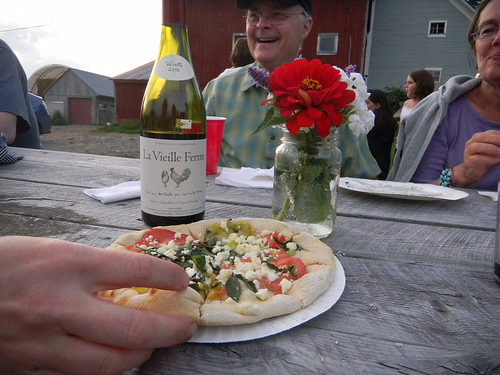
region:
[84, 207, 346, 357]
Small pizza over a white dish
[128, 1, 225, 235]
Bottle of wine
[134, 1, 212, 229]
Bottle of wine is half empty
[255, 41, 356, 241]
Jar with a flowers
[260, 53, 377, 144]
Red and white flowers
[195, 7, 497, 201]
Couple sitting on a table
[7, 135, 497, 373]
Table is made of wood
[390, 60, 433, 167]
A girl behind a couple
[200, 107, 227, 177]
Red plastic glass in front of man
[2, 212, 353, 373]
Hand taking a pizza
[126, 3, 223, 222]
Wine bottle on the table.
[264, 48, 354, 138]
Red flower in the jar.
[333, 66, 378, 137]
White flowers in the jar.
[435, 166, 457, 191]
Turquoise flower medallion on woman's wrist.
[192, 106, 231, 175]
Red plastic cup behind the wine bottle.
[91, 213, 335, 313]
Dough with cheese and tomatoes.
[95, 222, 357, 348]
White paper plate dough and tomato dish is on.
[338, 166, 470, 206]
Empty paper plate in front of woman in purple shirt.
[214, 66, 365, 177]
Yellow and blue shirt worn by older man.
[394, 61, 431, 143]
Young girl in white tank top behind older woman in purple shirt.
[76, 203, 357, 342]
small margherita pizza on plate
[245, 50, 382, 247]
flower arrangement in glass jar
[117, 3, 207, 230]
wine bottle with chickens on label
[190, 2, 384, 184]
man in plaid shird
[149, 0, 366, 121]
dark red building in background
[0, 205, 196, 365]
hand reaching for pizza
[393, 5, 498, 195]
woman with purple shirt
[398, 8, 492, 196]
woman with grey sweater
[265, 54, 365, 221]
red gerber daisy in jar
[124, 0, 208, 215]
red wine in bottle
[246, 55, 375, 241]
red zinnia in mason jar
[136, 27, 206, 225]
green glass bottle on table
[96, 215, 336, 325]
personal size pizza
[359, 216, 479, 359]
wood grain of picnic table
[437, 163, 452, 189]
turquoise bracelet on woman's wrist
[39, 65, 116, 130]
wood structure in background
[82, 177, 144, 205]
folded up white napkin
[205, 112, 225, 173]
red Solo cup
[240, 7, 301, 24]
eyeglasses on man's face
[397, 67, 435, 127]
young girl in white tank top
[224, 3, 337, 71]
the man is smiling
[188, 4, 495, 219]
people are in the photo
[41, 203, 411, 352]
pizza is on the table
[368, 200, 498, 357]
the table is of wood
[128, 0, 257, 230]
wine is in the bottle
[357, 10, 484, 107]
buildings are in the photo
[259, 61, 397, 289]
flower is in the vase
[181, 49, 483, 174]
the people are wearing clothes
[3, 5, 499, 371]
the photo is clear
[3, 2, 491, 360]
the photo was taken outside